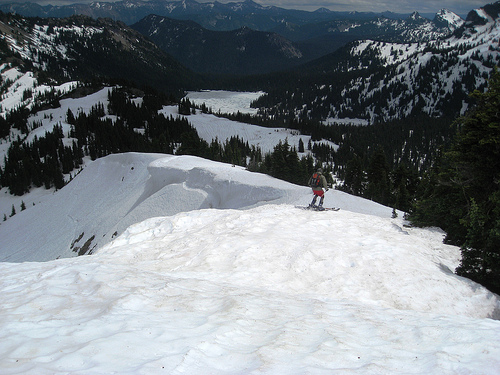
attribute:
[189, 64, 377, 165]
field — snowy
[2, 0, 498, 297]
forrest — evergreens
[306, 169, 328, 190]
backpack — red, black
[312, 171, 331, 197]
jacket — gray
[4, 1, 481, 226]
mountain range — large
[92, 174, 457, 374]
field — snowy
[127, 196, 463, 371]
field — snowy